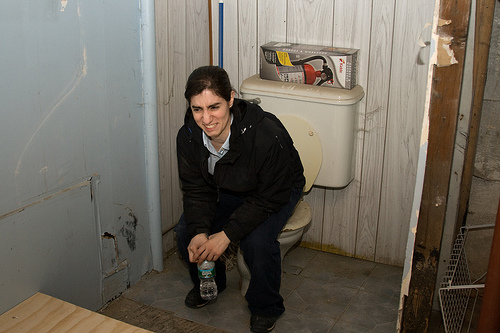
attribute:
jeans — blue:
[170, 187, 280, 328]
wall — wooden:
[22, 6, 119, 186]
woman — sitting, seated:
[164, 66, 303, 322]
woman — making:
[165, 64, 314, 264]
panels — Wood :
[208, 0, 430, 270]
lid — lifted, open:
[275, 110, 320, 195]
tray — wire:
[420, 207, 480, 331]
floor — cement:
[98, 244, 403, 327]